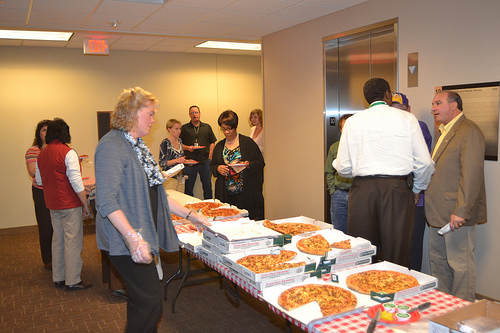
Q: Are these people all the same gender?
A: No, they are both male and female.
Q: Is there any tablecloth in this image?
A: Yes, there is a tablecloth.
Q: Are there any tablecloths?
A: Yes, there is a tablecloth.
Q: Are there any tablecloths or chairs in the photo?
A: Yes, there is a tablecloth.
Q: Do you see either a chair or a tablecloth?
A: Yes, there is a tablecloth.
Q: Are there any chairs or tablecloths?
A: Yes, there is a tablecloth.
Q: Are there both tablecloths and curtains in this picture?
A: No, there is a tablecloth but no curtains.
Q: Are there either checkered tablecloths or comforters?
A: Yes, there is a checkered tablecloth.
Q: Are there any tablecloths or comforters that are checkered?
A: Yes, the tablecloth is checkered.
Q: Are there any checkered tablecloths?
A: Yes, there is a checkered tablecloth.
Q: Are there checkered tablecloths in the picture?
A: Yes, there is a checkered tablecloth.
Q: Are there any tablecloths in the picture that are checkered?
A: Yes, there is a tablecloth that is checkered.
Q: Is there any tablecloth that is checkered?
A: Yes, there is a tablecloth that is checkered.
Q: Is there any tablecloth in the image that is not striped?
A: Yes, there is a checkered tablecloth.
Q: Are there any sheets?
A: No, there are no sheets.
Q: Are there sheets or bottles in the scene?
A: No, there are no sheets or bottles.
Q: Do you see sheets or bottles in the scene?
A: No, there are no sheets or bottles.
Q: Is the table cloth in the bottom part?
A: Yes, the table cloth is in the bottom of the image.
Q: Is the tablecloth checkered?
A: Yes, the tablecloth is checkered.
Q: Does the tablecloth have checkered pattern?
A: Yes, the tablecloth is checkered.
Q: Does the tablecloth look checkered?
A: Yes, the tablecloth is checkered.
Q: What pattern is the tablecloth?
A: The tablecloth is checkered.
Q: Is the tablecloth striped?
A: No, the tablecloth is checkered.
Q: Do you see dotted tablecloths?
A: No, there is a tablecloth but it is checkered.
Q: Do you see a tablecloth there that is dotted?
A: No, there is a tablecloth but it is checkered.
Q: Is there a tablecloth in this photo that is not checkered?
A: No, there is a tablecloth but it is checkered.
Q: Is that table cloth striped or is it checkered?
A: The table cloth is checkered.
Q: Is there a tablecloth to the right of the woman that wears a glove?
A: Yes, there is a tablecloth to the right of the woman.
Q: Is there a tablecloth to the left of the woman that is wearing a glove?
A: No, the tablecloth is to the right of the woman.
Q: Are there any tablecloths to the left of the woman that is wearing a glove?
A: No, the tablecloth is to the right of the woman.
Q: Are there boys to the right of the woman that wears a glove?
A: No, there is a tablecloth to the right of the woman.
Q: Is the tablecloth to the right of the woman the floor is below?
A: Yes, the tablecloth is to the right of the woman.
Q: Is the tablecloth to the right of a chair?
A: No, the tablecloth is to the right of the woman.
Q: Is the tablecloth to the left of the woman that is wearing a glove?
A: No, the tablecloth is to the right of the woman.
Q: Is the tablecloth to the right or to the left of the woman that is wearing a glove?
A: The tablecloth is to the right of the woman.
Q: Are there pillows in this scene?
A: No, there are no pillows.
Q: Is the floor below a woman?
A: Yes, the floor is below a woman.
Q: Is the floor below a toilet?
A: No, the floor is below a woman.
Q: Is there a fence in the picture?
A: No, there are no fences.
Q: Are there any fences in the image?
A: No, there are no fences.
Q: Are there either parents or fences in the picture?
A: No, there are no fences or parents.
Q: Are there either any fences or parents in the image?
A: No, there are no fences or parents.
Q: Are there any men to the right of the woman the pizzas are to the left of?
A: Yes, there is a man to the right of the woman.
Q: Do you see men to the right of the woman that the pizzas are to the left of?
A: Yes, there is a man to the right of the woman.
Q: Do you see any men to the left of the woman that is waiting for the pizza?
A: No, the man is to the right of the woman.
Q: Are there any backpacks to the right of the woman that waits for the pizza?
A: No, there is a man to the right of the woman.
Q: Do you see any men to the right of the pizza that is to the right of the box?
A: Yes, there is a man to the right of the pizza.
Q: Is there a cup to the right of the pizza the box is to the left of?
A: No, there is a man to the right of the pizza.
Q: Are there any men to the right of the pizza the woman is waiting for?
A: Yes, there is a man to the right of the pizza.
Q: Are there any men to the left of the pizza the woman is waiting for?
A: No, the man is to the right of the pizza.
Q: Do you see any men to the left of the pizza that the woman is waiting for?
A: No, the man is to the right of the pizza.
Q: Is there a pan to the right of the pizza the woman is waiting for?
A: No, there is a man to the right of the pizza.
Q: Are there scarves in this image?
A: Yes, there is a scarf.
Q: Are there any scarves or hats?
A: Yes, there is a scarf.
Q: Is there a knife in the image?
A: Yes, there is a knife.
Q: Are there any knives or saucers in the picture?
A: Yes, there is a knife.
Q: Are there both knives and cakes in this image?
A: No, there is a knife but no cakes.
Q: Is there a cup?
A: No, there are no cups.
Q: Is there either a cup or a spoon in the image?
A: No, there are no cups or spoons.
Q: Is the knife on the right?
A: Yes, the knife is on the right of the image.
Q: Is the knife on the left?
A: No, the knife is on the right of the image.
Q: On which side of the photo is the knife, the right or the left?
A: The knife is on the right of the image.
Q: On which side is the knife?
A: The knife is on the right of the image.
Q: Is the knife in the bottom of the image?
A: Yes, the knife is in the bottom of the image.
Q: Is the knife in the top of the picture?
A: No, the knife is in the bottom of the image.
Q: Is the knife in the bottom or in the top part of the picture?
A: The knife is in the bottom of the image.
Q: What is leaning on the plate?
A: The knife is leaning on the plate.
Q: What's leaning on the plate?
A: The knife is leaning on the plate.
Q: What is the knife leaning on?
A: The knife is leaning on the plate.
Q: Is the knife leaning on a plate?
A: Yes, the knife is leaning on a plate.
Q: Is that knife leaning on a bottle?
A: No, the knife is leaning on a plate.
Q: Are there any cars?
A: No, there are no cars.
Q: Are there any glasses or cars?
A: No, there are no cars or glasses.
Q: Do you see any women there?
A: Yes, there is a woman.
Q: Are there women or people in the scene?
A: Yes, there is a woman.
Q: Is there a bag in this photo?
A: No, there are no bags.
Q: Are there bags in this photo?
A: No, there are no bags.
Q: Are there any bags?
A: No, there are no bags.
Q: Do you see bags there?
A: No, there are no bags.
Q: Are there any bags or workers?
A: No, there are no bags or workers.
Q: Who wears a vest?
A: The woman wears a vest.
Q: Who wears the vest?
A: The woman wears a vest.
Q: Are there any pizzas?
A: Yes, there is a pizza.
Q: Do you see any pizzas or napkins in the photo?
A: Yes, there is a pizza.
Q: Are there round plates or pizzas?
A: Yes, there is a round pizza.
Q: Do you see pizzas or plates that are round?
A: Yes, the pizza is round.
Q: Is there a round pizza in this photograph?
A: Yes, there is a round pizza.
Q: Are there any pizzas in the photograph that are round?
A: Yes, there is a pizza that is round.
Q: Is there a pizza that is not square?
A: Yes, there is a round pizza.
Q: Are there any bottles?
A: No, there are no bottles.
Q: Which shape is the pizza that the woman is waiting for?
A: The pizza is round.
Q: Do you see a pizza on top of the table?
A: Yes, there is a pizza on top of the table.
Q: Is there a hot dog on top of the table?
A: No, there is a pizza on top of the table.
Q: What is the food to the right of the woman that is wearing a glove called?
A: The food is a pizza.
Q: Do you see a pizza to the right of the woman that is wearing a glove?
A: Yes, there is a pizza to the right of the woman.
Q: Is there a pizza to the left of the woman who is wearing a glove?
A: No, the pizza is to the right of the woman.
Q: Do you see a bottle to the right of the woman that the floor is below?
A: No, there is a pizza to the right of the woman.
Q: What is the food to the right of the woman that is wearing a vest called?
A: The food is a pizza.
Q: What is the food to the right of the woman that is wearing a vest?
A: The food is a pizza.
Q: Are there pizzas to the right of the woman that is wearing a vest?
A: Yes, there is a pizza to the right of the woman.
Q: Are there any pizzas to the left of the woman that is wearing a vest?
A: No, the pizza is to the right of the woman.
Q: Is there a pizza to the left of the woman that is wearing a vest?
A: No, the pizza is to the right of the woman.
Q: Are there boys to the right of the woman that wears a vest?
A: No, there is a pizza to the right of the woman.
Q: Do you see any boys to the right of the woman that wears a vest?
A: No, there is a pizza to the right of the woman.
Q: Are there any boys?
A: No, there are no boys.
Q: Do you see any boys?
A: No, there are no boys.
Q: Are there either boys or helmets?
A: No, there are no boys or helmets.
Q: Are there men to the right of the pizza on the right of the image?
A: Yes, there is a man to the right of the pizza.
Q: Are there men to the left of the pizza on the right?
A: No, the man is to the right of the pizza.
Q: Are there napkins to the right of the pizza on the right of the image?
A: No, there is a man to the right of the pizza.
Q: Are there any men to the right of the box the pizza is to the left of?
A: Yes, there is a man to the right of the box.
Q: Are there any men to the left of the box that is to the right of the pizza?
A: No, the man is to the right of the box.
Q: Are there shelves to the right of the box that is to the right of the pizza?
A: No, there is a man to the right of the box.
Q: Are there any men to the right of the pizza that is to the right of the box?
A: Yes, there is a man to the right of the pizza.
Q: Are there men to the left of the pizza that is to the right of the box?
A: No, the man is to the right of the pizza.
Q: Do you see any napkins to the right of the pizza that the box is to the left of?
A: No, there is a man to the right of the pizza.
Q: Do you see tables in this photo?
A: Yes, there is a table.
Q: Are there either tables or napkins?
A: Yes, there is a table.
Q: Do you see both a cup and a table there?
A: No, there is a table but no cups.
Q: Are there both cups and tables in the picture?
A: No, there is a table but no cups.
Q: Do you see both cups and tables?
A: No, there is a table but no cups.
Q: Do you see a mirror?
A: No, there are no mirrors.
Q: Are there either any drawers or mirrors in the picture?
A: No, there are no mirrors or drawers.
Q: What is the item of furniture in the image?
A: The piece of furniture is a table.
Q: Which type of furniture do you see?
A: The furniture is a table.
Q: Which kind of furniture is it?
A: The piece of furniture is a table.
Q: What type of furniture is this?
A: This is a table.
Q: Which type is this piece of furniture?
A: This is a table.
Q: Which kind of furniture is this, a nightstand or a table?
A: This is a table.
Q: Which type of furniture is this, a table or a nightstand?
A: This is a table.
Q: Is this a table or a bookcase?
A: This is a table.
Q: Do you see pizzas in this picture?
A: Yes, there is a pizza.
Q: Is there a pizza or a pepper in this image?
A: Yes, there is a pizza.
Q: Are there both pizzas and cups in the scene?
A: No, there is a pizza but no cups.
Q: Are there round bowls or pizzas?
A: Yes, there is a round pizza.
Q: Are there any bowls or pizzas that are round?
A: Yes, the pizza is round.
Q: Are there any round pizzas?
A: Yes, there is a round pizza.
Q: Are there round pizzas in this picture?
A: Yes, there is a round pizza.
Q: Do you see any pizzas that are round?
A: Yes, there is a pizza that is round.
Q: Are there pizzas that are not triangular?
A: Yes, there is a round pizza.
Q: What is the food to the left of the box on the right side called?
A: The food is a pizza.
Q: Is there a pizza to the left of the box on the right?
A: Yes, there is a pizza to the left of the box.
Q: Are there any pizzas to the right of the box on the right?
A: No, the pizza is to the left of the box.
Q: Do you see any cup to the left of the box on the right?
A: No, there is a pizza to the left of the box.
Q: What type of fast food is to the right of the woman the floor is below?
A: The food is a pizza.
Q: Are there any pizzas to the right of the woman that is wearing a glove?
A: Yes, there is a pizza to the right of the woman.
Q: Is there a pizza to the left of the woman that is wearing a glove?
A: No, the pizza is to the right of the woman.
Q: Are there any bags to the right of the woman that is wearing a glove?
A: No, there is a pizza to the right of the woman.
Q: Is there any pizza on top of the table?
A: Yes, there is a pizza on top of the table.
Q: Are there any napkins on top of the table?
A: No, there is a pizza on top of the table.